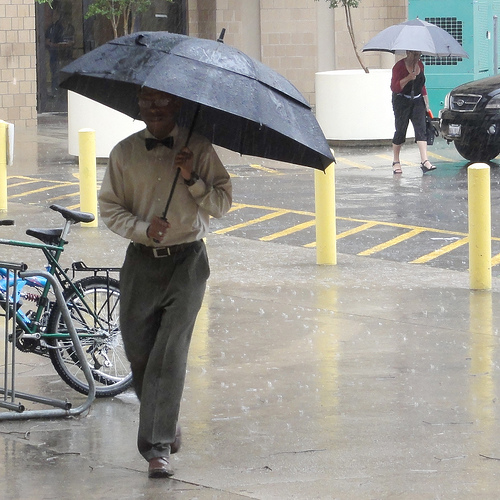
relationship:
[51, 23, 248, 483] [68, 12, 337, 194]
man holding umbrella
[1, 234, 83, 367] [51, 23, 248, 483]
bikes are behind man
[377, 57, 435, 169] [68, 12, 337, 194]
woman walking with umbrella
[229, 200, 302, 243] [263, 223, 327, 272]
lines are on street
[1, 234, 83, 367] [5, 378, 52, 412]
bikes attached to rack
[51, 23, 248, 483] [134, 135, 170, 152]
man wearing bow tie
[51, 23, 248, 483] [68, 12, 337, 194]
man carrying umbrella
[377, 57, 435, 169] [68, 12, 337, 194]
woman carrying umbrella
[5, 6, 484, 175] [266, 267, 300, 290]
rain on sidewalk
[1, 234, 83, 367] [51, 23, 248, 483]
bikes next to man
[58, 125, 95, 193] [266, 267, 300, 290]
pole on sidewalk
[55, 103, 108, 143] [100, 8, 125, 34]
container for tree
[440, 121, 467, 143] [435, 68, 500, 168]
bumper on suv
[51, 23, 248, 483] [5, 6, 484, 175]
man in rain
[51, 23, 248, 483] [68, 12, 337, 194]
man has umbrella